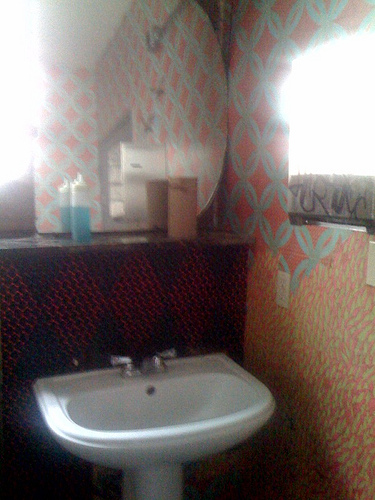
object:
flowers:
[232, 52, 266, 115]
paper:
[232, 7, 365, 484]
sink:
[35, 347, 273, 449]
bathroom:
[0, 0, 373, 497]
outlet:
[275, 268, 290, 307]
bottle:
[70, 173, 91, 244]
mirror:
[288, 40, 375, 179]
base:
[119, 466, 187, 499]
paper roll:
[165, 170, 199, 240]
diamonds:
[185, 94, 204, 131]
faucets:
[110, 356, 142, 380]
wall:
[276, 221, 367, 499]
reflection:
[60, 179, 71, 233]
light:
[287, 48, 374, 177]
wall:
[210, 9, 286, 234]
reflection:
[86, 20, 229, 214]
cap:
[121, 146, 167, 181]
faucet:
[139, 347, 178, 375]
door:
[99, 110, 135, 227]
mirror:
[42, 2, 230, 226]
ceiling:
[35, 1, 129, 71]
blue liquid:
[70, 206, 91, 242]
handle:
[111, 354, 133, 365]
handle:
[158, 349, 176, 358]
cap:
[71, 172, 88, 189]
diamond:
[234, 118, 259, 171]